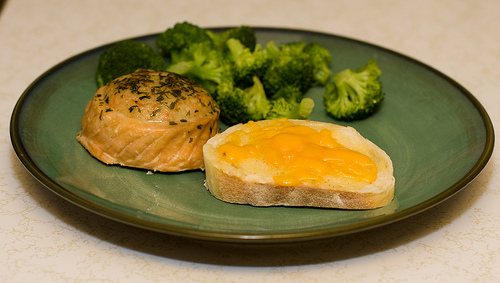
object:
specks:
[94, 71, 232, 126]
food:
[80, 67, 226, 175]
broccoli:
[326, 62, 386, 118]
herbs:
[92, 69, 218, 129]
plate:
[9, 22, 497, 247]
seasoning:
[89, 66, 221, 122]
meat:
[75, 96, 217, 172]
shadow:
[77, 166, 134, 204]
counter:
[0, 2, 497, 278]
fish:
[77, 66, 223, 173]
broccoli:
[93, 20, 386, 122]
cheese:
[221, 117, 380, 191]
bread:
[203, 117, 398, 210]